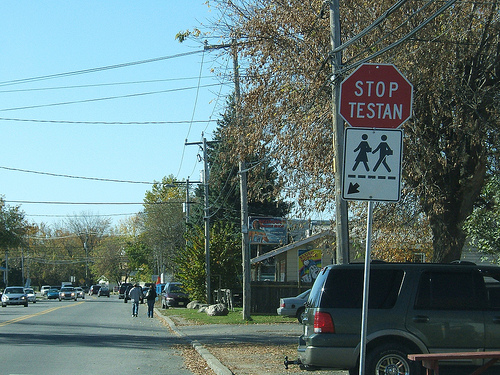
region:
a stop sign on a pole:
[323, 51, 420, 135]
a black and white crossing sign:
[326, 118, 415, 216]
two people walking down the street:
[119, 276, 164, 327]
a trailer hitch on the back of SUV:
[275, 349, 304, 373]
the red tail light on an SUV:
[308, 309, 339, 339]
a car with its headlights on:
[57, 283, 79, 304]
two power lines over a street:
[39, 159, 164, 216]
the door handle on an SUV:
[407, 306, 435, 328]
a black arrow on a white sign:
[342, 176, 366, 201]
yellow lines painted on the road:
[10, 308, 40, 327]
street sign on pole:
[326, 52, 413, 373]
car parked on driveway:
[288, 234, 498, 370]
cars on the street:
[5, 272, 85, 314]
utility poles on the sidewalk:
[186, 129, 229, 304]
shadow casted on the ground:
[8, 318, 168, 357]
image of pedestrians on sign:
[349, 132, 395, 182]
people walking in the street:
[123, 276, 164, 324]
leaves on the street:
[173, 342, 213, 373]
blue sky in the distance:
[33, 123, 154, 168]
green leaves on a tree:
[154, 177, 203, 264]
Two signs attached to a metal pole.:
[337, 62, 413, 374]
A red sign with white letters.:
[336, 60, 413, 129]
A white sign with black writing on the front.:
[345, 124, 402, 203]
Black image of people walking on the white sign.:
[350, 132, 395, 174]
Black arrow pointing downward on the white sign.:
[344, 179, 361, 198]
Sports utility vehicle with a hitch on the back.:
[282, 257, 499, 373]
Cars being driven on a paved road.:
[0, 281, 210, 374]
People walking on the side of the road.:
[128, 281, 158, 319]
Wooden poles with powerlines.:
[1, 27, 268, 322]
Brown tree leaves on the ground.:
[143, 299, 335, 374]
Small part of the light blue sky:
[103, 136, 125, 156]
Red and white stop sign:
[333, 60, 419, 127]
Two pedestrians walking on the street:
[126, 280, 160, 316]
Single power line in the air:
[65, 113, 152, 130]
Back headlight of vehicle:
[311, 310, 330, 334]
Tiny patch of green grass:
[201, 312, 209, 323]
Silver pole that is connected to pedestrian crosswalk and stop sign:
[356, 248, 371, 373]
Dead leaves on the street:
[185, 351, 198, 371]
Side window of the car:
[423, 274, 477, 309]